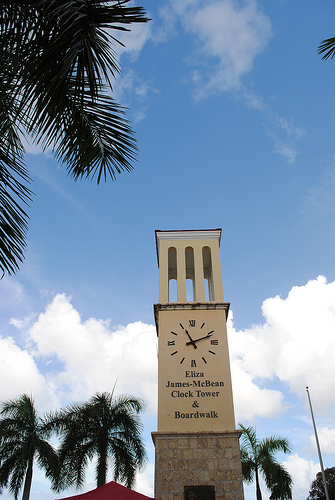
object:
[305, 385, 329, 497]
flag pole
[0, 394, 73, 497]
palm tree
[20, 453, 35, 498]
trunk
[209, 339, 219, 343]
roman numeral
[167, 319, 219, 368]
clock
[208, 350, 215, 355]
roman numeral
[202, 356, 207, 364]
roman numeral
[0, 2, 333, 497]
sky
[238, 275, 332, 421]
clouds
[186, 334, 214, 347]
hand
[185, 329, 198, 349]
hand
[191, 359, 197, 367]
roman numeral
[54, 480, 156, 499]
roof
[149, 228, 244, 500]
tower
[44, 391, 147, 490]
tree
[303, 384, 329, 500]
pole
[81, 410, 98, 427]
leaves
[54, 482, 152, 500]
tent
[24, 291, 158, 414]
cloud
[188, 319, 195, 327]
roman numeral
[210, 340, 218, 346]
roman numeral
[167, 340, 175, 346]
roman numeral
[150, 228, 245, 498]
building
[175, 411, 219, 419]
word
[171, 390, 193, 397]
word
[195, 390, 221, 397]
word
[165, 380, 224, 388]
word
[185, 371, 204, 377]
word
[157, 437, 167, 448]
brick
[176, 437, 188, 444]
brick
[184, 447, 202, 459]
brick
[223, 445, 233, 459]
brick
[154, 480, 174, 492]
brick